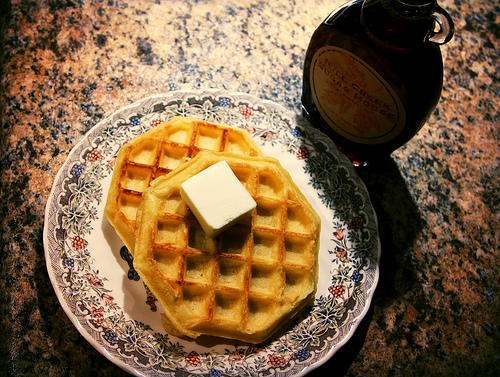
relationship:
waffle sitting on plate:
[104, 116, 321, 345] [41, 89, 380, 376]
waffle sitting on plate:
[106, 114, 264, 258] [41, 89, 380, 376]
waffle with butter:
[104, 116, 321, 345] [179, 160, 257, 239]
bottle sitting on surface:
[289, 0, 464, 164] [1, 1, 499, 376]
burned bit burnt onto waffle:
[127, 160, 157, 169] [106, 114, 264, 258]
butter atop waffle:
[179, 160, 257, 239] [104, 116, 321, 345]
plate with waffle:
[41, 89, 380, 376] [104, 116, 321, 345]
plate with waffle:
[41, 89, 380, 376] [106, 114, 264, 258]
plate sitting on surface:
[41, 89, 380, 376] [1, 1, 499, 376]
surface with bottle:
[1, 1, 499, 376] [289, 0, 464, 164]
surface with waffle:
[1, 1, 499, 376] [104, 116, 321, 345]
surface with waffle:
[1, 1, 499, 376] [106, 114, 264, 258]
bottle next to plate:
[289, 0, 464, 164] [41, 89, 380, 376]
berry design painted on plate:
[71, 162, 85, 178] [41, 89, 380, 376]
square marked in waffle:
[252, 228, 279, 261] [104, 116, 321, 345]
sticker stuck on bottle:
[309, 44, 404, 143] [289, 0, 464, 164]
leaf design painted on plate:
[57, 196, 91, 234] [41, 89, 380, 376]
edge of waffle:
[308, 215, 319, 301] [104, 116, 321, 345]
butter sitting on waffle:
[179, 160, 257, 239] [104, 116, 321, 345]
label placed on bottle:
[309, 44, 404, 143] [289, 0, 464, 164]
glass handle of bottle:
[423, 5, 454, 46] [289, 0, 464, 164]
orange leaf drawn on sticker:
[320, 49, 393, 136] [309, 44, 404, 143]